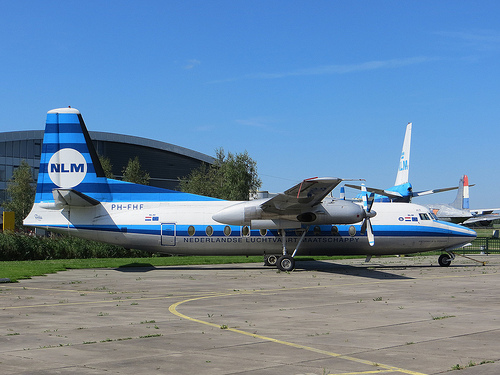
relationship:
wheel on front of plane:
[437, 255, 450, 267] [18, 103, 479, 273]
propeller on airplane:
[357, 184, 382, 250] [23, 102, 476, 282]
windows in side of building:
[1, 142, 40, 178] [6, 129, 246, 206]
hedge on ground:
[197, 155, 257, 188] [2, 258, 495, 359]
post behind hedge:
[10, 197, 114, 292] [168, 161, 272, 201]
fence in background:
[462, 234, 499, 255] [1, 302, 493, 372]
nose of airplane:
[411, 157, 480, 264] [428, 171, 500, 227]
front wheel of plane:
[436, 252, 451, 266] [18, 103, 479, 273]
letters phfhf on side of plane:
[95, 185, 159, 245] [0, 108, 494, 252]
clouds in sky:
[0, 2, 498, 97] [5, 7, 480, 132]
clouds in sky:
[184, 29, 498, 213] [1, 1, 499, 213]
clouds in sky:
[0, 2, 498, 97] [1, 1, 499, 213]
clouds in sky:
[0, 2, 498, 97] [17, 6, 497, 74]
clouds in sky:
[0, 2, 498, 97] [195, 15, 472, 165]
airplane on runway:
[23, 102, 476, 282] [6, 257, 498, 367]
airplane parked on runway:
[342, 120, 476, 202] [29, 254, 494, 363]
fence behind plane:
[462, 234, 497, 253] [28, 79, 493, 300]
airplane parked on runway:
[23, 102, 476, 282] [6, 257, 498, 367]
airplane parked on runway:
[342, 120, 476, 202] [6, 257, 498, 367]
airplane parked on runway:
[428, 177, 496, 236] [6, 257, 498, 367]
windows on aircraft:
[418, 209, 433, 220] [19, 104, 479, 272]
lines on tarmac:
[240, 330, 335, 360] [27, 283, 498, 360]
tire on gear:
[275, 254, 297, 271] [266, 221, 317, 255]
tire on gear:
[264, 250, 280, 267] [266, 221, 317, 255]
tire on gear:
[436, 252, 455, 269] [266, 221, 317, 255]